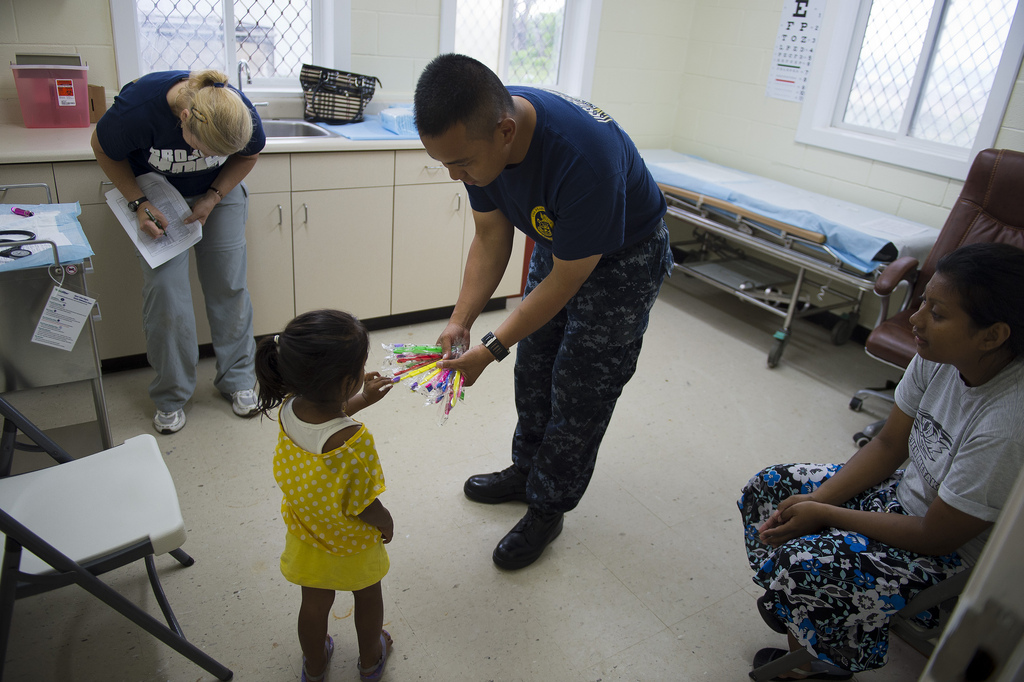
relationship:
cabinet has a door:
[227, 122, 398, 323] [289, 180, 402, 312]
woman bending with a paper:
[97, 68, 333, 252] [75, 147, 220, 303]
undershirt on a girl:
[266, 398, 359, 465] [222, 245, 436, 518]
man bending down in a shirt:
[354, 18, 676, 280] [471, 95, 638, 309]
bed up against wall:
[622, 124, 927, 358] [576, 16, 1022, 401]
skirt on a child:
[261, 510, 393, 591] [249, 310, 396, 682]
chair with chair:
[8, 387, 225, 677] [0, 395, 235, 681]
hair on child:
[233, 303, 398, 431] [231, 290, 387, 571]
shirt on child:
[248, 420, 396, 604] [237, 279, 426, 569]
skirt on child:
[280, 530, 390, 591] [155, 247, 430, 537]